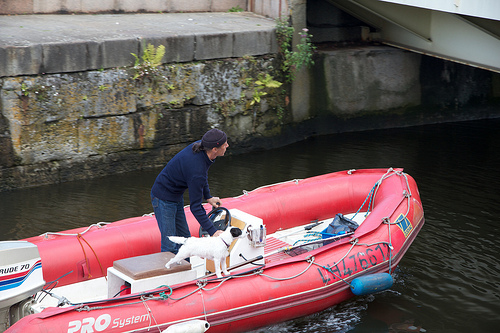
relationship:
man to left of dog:
[152, 127, 230, 255] [169, 228, 247, 278]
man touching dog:
[152, 127, 230, 255] [169, 228, 247, 278]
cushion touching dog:
[114, 249, 190, 280] [169, 228, 247, 278]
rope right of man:
[350, 181, 378, 225] [152, 127, 230, 255]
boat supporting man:
[6, 165, 425, 332] [152, 127, 230, 255]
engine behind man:
[0, 242, 47, 331] [152, 127, 230, 255]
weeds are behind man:
[133, 44, 166, 84] [152, 127, 230, 255]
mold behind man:
[19, 86, 67, 120] [152, 127, 230, 255]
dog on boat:
[169, 228, 247, 278] [6, 165, 425, 332]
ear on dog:
[233, 228, 240, 237] [169, 228, 247, 278]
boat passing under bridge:
[6, 165, 425, 332] [349, 2, 499, 77]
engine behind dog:
[0, 242, 47, 331] [169, 228, 247, 278]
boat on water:
[6, 165, 425, 332] [278, 130, 500, 332]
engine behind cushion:
[0, 242, 47, 331] [114, 249, 190, 280]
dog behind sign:
[169, 228, 247, 278] [397, 212, 414, 239]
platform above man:
[4, 9, 281, 49] [152, 127, 230, 255]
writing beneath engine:
[63, 310, 152, 332] [0, 242, 47, 331]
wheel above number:
[199, 203, 231, 239] [319, 240, 392, 288]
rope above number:
[350, 181, 378, 225] [319, 240, 392, 288]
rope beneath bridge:
[350, 181, 378, 225] [349, 2, 499, 77]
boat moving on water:
[6, 165, 425, 332] [278, 130, 500, 332]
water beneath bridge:
[278, 130, 500, 332] [349, 2, 499, 77]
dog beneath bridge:
[169, 228, 247, 278] [349, 2, 499, 77]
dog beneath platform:
[169, 228, 247, 278] [4, 9, 281, 49]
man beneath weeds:
[152, 127, 230, 255] [133, 44, 166, 84]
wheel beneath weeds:
[199, 203, 231, 239] [133, 44, 166, 84]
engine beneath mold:
[0, 242, 47, 331] [19, 86, 67, 120]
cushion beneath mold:
[114, 249, 190, 280] [19, 86, 67, 120]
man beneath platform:
[152, 127, 230, 255] [4, 9, 281, 49]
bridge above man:
[349, 2, 499, 77] [152, 127, 230, 255]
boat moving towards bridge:
[6, 165, 425, 332] [349, 2, 499, 77]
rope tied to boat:
[350, 181, 378, 225] [6, 165, 425, 332]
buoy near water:
[349, 272, 395, 295] [278, 130, 500, 332]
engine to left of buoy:
[0, 242, 47, 331] [349, 272, 395, 295]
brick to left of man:
[3, 56, 292, 168] [152, 127, 230, 255]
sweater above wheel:
[154, 146, 220, 235] [199, 203, 231, 239]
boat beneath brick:
[6, 165, 425, 332] [3, 56, 292, 168]